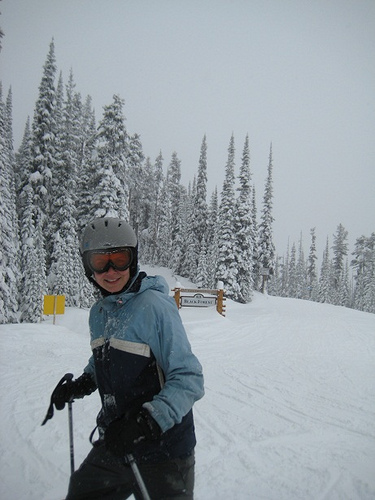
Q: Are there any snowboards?
A: No, there are no snowboards.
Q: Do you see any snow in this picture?
A: Yes, there is snow.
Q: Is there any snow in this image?
A: Yes, there is snow.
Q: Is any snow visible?
A: Yes, there is snow.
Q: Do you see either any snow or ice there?
A: Yes, there is snow.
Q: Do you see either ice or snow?
A: Yes, there is snow.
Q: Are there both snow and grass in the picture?
A: No, there is snow but no grass.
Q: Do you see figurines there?
A: No, there are no figurines.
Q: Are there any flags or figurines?
A: No, there are no figurines or flags.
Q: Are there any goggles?
A: Yes, there are goggles.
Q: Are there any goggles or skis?
A: Yes, there are goggles.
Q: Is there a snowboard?
A: No, there are no snowboards.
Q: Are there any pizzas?
A: Yes, there is a pizza.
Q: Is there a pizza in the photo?
A: Yes, there is a pizza.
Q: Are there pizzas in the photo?
A: Yes, there is a pizza.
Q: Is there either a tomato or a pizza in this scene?
A: Yes, there is a pizza.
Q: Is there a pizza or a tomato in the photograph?
A: Yes, there is a pizza.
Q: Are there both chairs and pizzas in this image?
A: No, there is a pizza but no chairs.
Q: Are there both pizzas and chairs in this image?
A: No, there is a pizza but no chairs.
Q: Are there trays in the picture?
A: No, there are no trays.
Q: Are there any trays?
A: No, there are no trays.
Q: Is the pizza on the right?
A: Yes, the pizza is on the right of the image.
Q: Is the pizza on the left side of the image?
A: No, the pizza is on the right of the image.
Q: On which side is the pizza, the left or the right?
A: The pizza is on the right of the image.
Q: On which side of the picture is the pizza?
A: The pizza is on the right of the image.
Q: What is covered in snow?
A: The pine is covered in snow.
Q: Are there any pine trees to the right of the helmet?
A: Yes, there is a pine tree to the right of the helmet.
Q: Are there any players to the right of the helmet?
A: No, there is a pine tree to the right of the helmet.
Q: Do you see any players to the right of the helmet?
A: No, there is a pine tree to the right of the helmet.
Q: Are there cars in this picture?
A: No, there are no cars.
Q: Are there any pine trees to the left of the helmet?
A: Yes, there is a pine tree to the left of the helmet.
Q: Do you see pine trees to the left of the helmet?
A: Yes, there is a pine tree to the left of the helmet.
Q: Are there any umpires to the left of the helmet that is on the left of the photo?
A: No, there is a pine tree to the left of the helmet.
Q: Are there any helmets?
A: Yes, there is a helmet.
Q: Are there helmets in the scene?
A: Yes, there is a helmet.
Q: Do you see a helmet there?
A: Yes, there is a helmet.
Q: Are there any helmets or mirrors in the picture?
A: Yes, there is a helmet.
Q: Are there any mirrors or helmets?
A: Yes, there is a helmet.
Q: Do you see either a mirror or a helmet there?
A: Yes, there is a helmet.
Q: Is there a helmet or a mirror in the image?
A: Yes, there is a helmet.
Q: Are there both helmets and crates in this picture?
A: No, there is a helmet but no crates.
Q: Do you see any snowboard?
A: No, there are no snowboards.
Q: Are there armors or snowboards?
A: No, there are no snowboards or armors.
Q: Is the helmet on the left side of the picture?
A: Yes, the helmet is on the left of the image.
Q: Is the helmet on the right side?
A: No, the helmet is on the left of the image.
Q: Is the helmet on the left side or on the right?
A: The helmet is on the left of the image.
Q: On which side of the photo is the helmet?
A: The helmet is on the left of the image.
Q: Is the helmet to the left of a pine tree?
A: Yes, the helmet is to the left of a pine tree.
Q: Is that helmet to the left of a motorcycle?
A: No, the helmet is to the left of a pine tree.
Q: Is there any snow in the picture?
A: Yes, there is snow.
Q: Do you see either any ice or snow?
A: Yes, there is snow.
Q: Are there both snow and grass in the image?
A: No, there is snow but no grass.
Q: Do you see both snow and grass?
A: No, there is snow but no grass.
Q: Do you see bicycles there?
A: No, there are no bicycles.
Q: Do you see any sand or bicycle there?
A: No, there are no bicycles or sand.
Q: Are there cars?
A: No, there are no cars.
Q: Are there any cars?
A: No, there are no cars.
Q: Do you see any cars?
A: No, there are no cars.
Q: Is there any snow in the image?
A: Yes, there is snow.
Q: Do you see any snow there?
A: Yes, there is snow.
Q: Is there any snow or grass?
A: Yes, there is snow.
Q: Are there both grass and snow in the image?
A: No, there is snow but no grass.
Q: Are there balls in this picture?
A: No, there are no balls.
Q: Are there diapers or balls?
A: No, there are no balls or diapers.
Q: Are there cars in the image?
A: No, there are no cars.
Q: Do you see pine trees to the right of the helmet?
A: Yes, there is a pine tree to the right of the helmet.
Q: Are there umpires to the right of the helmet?
A: No, there is a pine tree to the right of the helmet.